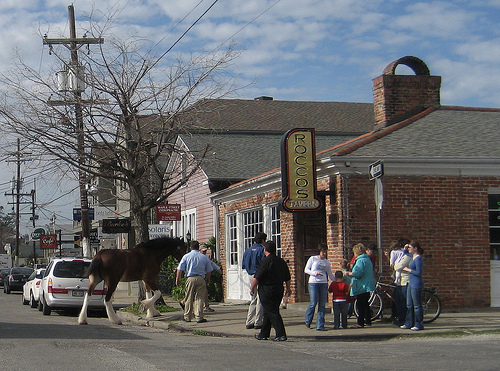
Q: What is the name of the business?
A: Roccos.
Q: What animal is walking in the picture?
A: Horse.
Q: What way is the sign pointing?
A: One way.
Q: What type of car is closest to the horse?
A: Van.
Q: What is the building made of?
A: Brick.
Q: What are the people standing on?
A: Sidewalk.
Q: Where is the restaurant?
A: Corner.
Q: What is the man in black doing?
A: Walking.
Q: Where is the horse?
A: On the side of the road.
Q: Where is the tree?
A: On the sidewalk.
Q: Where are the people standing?
A: On the sidewalk.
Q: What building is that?
A: Roccos.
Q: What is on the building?
A: A sign.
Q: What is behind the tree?
A: A electrical post.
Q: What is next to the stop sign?
A: A bike.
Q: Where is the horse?
A: Sidewalk.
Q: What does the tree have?
A: No leaves.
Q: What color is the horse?
A: Brown.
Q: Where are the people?
A: Outside a tavern.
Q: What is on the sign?
A: An arrow.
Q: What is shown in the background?
A: Shops.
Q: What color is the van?
A: White.